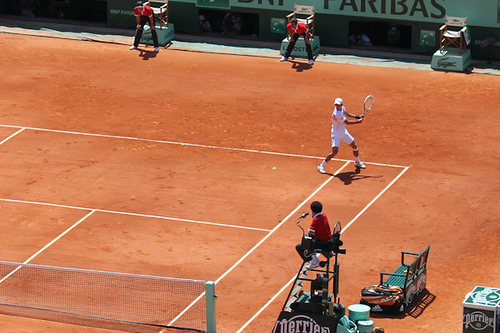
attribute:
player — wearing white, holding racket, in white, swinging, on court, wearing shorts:
[319, 93, 378, 179]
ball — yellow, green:
[272, 166, 280, 172]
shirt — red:
[313, 214, 331, 240]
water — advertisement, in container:
[465, 284, 499, 330]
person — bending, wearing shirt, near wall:
[130, 4, 159, 53]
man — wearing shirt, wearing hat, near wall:
[284, 18, 318, 66]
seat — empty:
[438, 17, 472, 55]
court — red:
[3, 34, 490, 270]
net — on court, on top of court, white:
[2, 261, 216, 332]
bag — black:
[363, 284, 405, 313]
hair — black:
[310, 203, 323, 213]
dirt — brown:
[3, 35, 327, 162]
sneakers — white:
[318, 165, 372, 173]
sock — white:
[322, 159, 328, 169]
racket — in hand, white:
[364, 93, 374, 118]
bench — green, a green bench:
[380, 247, 434, 310]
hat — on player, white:
[335, 99, 345, 107]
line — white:
[22, 123, 315, 172]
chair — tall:
[283, 249, 344, 311]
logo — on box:
[462, 312, 499, 330]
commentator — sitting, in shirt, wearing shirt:
[297, 201, 333, 269]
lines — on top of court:
[2, 199, 268, 281]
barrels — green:
[348, 301, 374, 332]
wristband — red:
[355, 119, 360, 125]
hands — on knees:
[287, 36, 311, 49]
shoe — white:
[356, 165, 369, 171]